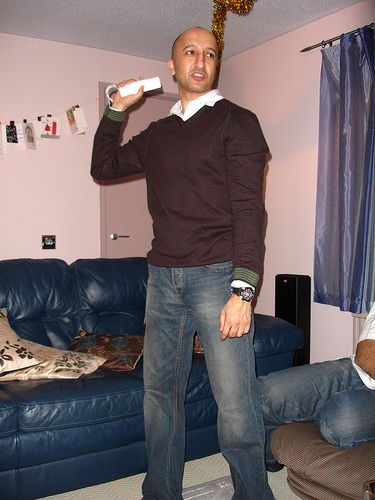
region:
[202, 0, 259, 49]
Christmas tinsil hanging from the ceiling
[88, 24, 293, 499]
Man holding a WII control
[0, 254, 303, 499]
Black leather couch behind the man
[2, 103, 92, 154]
Christmas cards taped to the wall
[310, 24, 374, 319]
Blue satin curtins on the right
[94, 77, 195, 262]
Entry door to the dwelling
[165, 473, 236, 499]
Grey throw rug under the man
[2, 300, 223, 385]
Throw pillows on the couch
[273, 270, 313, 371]
Large speaker on the wall behind the man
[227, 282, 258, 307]
Black watch on the man playing WII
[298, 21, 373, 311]
blue sheer curtain on narrow rod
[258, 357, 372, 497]
legs of a person sitting in a chair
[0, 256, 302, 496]
blue couch of a material resembling leather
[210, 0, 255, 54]
gold colored tinsel hung from ceiling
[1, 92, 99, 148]
strung greeting cards hung in front of wall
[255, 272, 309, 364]
black speaker to the right of couch arm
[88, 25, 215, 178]
man holding a white game controller behind his head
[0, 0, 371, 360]
walls of room are pale pink, while ceiling is white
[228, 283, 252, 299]
black wrist watch on man's left wrist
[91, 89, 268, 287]
man wearing a white shirt beneath his dark one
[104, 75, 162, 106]
man holding a gaming controller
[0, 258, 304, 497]
a blue leather couch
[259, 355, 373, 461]
a man wearing jeans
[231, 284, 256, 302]
a man wearing a watch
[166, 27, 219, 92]
a bald man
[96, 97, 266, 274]
man wearing a brown sweater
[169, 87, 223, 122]
a white collar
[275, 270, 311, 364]
a black speaker against a white wall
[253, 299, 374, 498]
a man sitting on an armchair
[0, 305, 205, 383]
various cushions on a blue leather couch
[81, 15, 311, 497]
this man is playing a video game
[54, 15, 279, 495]
this man is playing a Nintendo game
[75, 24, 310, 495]
a guy playing a game on the Wii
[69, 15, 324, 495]
a guy playing the Nintendo Wii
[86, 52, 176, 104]
a white Nintendo Wii controller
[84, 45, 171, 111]
a controller for a video game console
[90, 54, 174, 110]
a wireless video game controller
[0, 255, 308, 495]
a black leather couch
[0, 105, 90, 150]
Christmas cards hanging on string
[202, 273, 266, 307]
a large black watch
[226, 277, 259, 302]
black watch on wrist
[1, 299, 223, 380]
throw pillows on leather sofa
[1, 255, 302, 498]
blue leather sofa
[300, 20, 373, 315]
sheer purple curtain over window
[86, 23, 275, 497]
man holding white wii remote control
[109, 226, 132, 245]
metal handle of door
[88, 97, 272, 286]
brown v neck sweater with green cuffs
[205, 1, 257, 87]
gold christmas decoration on ceiling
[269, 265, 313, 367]
black upright object against wall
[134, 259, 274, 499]
pair of blue jeans